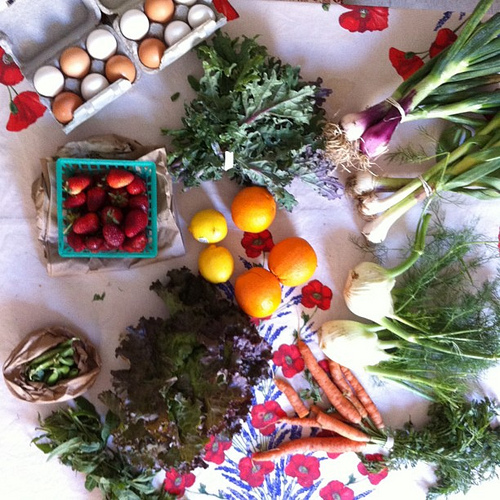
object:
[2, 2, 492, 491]
food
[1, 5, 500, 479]
cloth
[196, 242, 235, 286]
lemons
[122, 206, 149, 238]
strawberries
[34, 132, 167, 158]
paper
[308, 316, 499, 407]
fennel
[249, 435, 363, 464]
carrots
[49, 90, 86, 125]
eggs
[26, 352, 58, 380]
beans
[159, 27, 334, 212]
vegetables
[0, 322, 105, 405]
bag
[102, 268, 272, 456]
lettuce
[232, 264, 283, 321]
oranges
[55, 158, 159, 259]
box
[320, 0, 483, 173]
onions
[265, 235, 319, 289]
fruit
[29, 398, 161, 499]
greens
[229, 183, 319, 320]
threes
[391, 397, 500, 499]
leafy